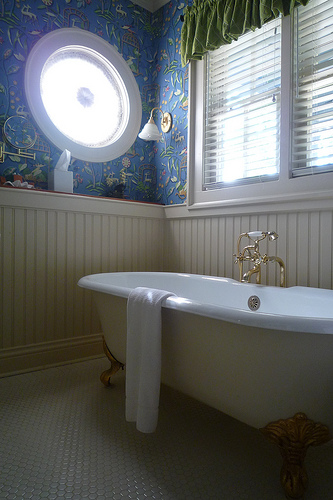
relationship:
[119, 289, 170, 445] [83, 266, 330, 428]
towel on bathtub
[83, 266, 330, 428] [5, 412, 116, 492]
bathtub on floor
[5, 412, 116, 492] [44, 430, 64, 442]
floor has tiles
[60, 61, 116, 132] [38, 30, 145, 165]
sunlight in window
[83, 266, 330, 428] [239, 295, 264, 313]
tub has drain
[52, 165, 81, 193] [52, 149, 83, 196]
box has tissues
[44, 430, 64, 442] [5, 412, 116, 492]
tiles are on floor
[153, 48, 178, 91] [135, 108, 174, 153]
wall has light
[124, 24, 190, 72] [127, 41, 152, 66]
wallpaper has design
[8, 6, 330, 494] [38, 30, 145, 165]
bathroom has window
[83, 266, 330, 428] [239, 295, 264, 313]
bathtub has drain